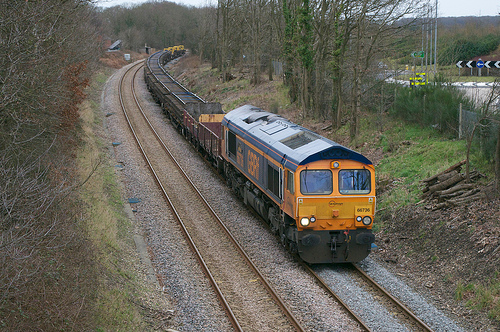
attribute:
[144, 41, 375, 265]
train — orange, carrier, flatbed, yellow, light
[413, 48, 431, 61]
sign — green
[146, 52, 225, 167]
cars — brown, train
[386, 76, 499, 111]
lot — parking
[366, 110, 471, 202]
coutryside — green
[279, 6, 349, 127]
tree — green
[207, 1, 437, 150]
trees — green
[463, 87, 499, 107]
area — paved